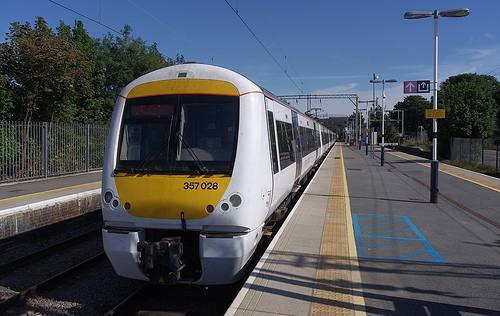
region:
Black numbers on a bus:
[174, 172, 234, 189]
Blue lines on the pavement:
[345, 196, 447, 282]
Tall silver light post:
[397, 5, 467, 205]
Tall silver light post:
[361, 69, 403, 171]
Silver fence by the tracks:
[15, 115, 62, 180]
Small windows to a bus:
[118, 92, 237, 182]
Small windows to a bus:
[263, 108, 294, 179]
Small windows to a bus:
[288, 114, 320, 159]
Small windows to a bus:
[312, 124, 344, 156]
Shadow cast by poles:
[270, 234, 484, 307]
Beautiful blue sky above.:
[280, 13, 351, 56]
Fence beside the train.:
[20, 120, 93, 177]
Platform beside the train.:
[26, 171, 101, 208]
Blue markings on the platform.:
[343, 186, 448, 278]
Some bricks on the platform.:
[312, 171, 344, 313]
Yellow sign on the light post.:
[419, 103, 452, 125]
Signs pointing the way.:
[400, 70, 433, 102]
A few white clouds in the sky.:
[442, 40, 496, 71]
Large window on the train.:
[110, 88, 249, 172]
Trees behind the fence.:
[8, 20, 147, 111]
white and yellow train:
[103, 64, 337, 281]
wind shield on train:
[118, 96, 239, 168]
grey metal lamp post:
[403, 8, 470, 204]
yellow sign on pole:
[426, 108, 446, 118]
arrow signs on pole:
[405, 80, 430, 95]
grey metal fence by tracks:
[1, 119, 113, 183]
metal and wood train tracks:
[93, 282, 237, 314]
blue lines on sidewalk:
[353, 210, 446, 267]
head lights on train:
[203, 193, 243, 213]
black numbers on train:
[183, 181, 217, 191]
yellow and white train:
[110, 63, 287, 273]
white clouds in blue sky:
[147, 9, 187, 36]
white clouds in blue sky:
[222, 12, 260, 39]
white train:
[231, 71, 329, 199]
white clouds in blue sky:
[278, 3, 319, 40]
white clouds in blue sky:
[284, 56, 336, 81]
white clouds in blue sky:
[344, 25, 376, 63]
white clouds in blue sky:
[357, 41, 407, 63]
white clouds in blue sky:
[458, 32, 480, 66]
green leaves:
[451, 86, 495, 111]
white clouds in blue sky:
[197, 8, 237, 32]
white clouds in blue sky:
[231, 15, 281, 66]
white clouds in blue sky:
[277, 12, 312, 100]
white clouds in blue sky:
[287, 19, 317, 56]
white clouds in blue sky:
[380, 33, 414, 68]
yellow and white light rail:
[131, 71, 271, 253]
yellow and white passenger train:
[81, 49, 256, 289]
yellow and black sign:
[418, 96, 446, 130]